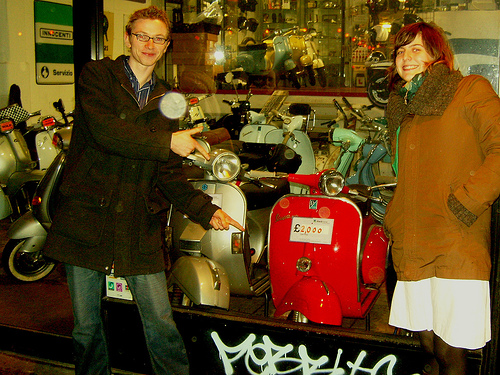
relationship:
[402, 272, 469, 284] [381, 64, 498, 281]
edge on coat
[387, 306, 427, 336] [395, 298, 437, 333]
edge of short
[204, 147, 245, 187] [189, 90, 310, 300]
headlight of scooter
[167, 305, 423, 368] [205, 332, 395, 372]
panel with graffiti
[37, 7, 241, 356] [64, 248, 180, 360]
man wears jeans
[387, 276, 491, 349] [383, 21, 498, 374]
short worn people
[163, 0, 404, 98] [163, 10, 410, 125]
mirror on wall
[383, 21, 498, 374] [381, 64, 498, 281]
people wears coat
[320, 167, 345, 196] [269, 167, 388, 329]
headlight on scooter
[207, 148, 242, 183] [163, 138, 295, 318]
headlight on scooter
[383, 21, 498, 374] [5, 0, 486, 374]
people in scooter store